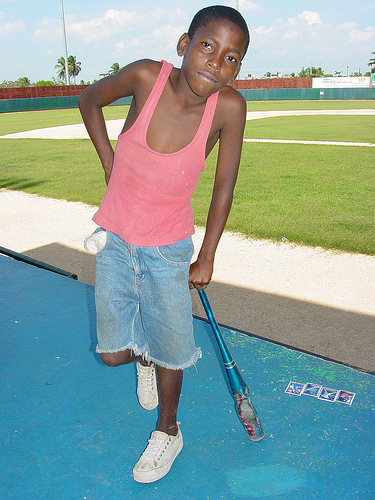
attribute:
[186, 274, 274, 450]
bat — blue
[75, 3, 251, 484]
boy — posing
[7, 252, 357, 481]
floor — blue